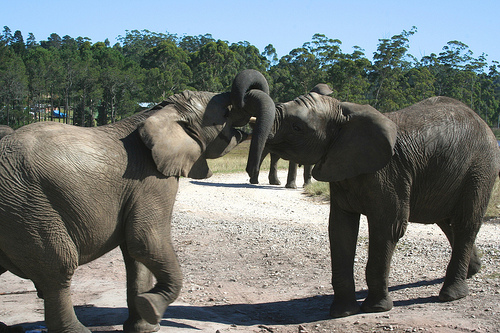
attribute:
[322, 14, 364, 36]
sky — blue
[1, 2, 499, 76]
sky — blue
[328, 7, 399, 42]
clouds — white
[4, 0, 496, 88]
sky — blue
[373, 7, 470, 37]
clouds — white 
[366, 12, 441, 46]
sky — blue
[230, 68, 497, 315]
elephant — large, gray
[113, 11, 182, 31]
sky — blue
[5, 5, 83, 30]
clouds — white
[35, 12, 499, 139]
trees — green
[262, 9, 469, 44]
sky — blue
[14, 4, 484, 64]
sky — blue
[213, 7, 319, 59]
clouds — white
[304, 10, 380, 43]
clouds — white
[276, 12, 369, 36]
clouds — white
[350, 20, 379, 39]
cloud — white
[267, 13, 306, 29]
cloud — white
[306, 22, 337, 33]
cloud — white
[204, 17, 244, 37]
cloud — white